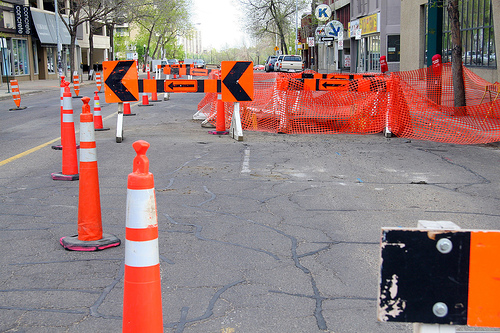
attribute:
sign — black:
[377, 219, 498, 329]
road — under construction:
[0, 69, 498, 331]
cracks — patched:
[141, 145, 329, 324]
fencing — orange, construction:
[238, 59, 498, 144]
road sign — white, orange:
[50, 59, 177, 331]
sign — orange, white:
[71, 69, 82, 97]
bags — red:
[372, 51, 443, 70]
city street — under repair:
[1, 61, 494, 331]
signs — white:
[313, 2, 331, 20]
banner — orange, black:
[376, 223, 498, 328]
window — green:
[418, 0, 496, 71]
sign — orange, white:
[100, 32, 274, 114]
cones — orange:
[104, 127, 198, 330]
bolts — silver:
[426, 223, 476, 311]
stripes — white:
[122, 182, 162, 266]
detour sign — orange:
[100, 60, 141, 105]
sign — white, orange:
[83, 51, 263, 111]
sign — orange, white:
[70, 53, 266, 149]